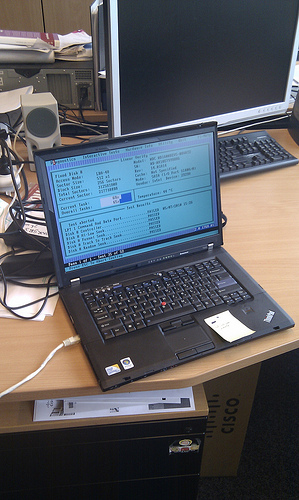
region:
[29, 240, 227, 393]
a black computer on the table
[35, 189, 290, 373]
a black computer on the table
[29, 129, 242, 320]
a black computer on the table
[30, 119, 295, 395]
One black laptop sitting on the desk.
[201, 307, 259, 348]
Yellow post it stuck to the key board.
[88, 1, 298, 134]
One large computer monitor sitting on the desk.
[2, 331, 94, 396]
White cable plugged into the laptop.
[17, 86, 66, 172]
Beige colored computer speaker.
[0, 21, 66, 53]
Textbook sitting on top of some paper.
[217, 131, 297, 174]
Black computer keyboard.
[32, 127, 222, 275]
Monitor of the laptop open and running.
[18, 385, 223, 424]
Stack of papers sitting on the shelf.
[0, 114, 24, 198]
White power supply with multiple plugs coming out of it.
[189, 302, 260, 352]
A post note on the computer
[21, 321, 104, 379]
an ethernet cable in the computer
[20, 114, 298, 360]
a laptop on the desk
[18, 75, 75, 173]
a speaker on the desk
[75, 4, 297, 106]
a monitor on the desk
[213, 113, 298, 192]
a keyboard on the desk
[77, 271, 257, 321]
a keyboard on the laptop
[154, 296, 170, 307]
a mouse button on the laptop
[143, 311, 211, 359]
a mouse pad on the laptop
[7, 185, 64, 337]
cables bundled up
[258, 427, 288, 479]
the floor is black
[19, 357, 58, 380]
the cord is white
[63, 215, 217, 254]
the laptop is on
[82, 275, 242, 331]
the laptop has a keyboard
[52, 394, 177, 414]
the papers are white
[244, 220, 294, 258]
the desk is brown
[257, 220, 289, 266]
the desk is wooden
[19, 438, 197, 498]
the cabinet is black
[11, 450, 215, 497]
the cabinet is under the desk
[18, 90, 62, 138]
the speaker is white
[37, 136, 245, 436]
a black laptop on a desk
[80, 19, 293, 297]
a computer monitor on a desk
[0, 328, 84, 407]
a cable connected to a laptop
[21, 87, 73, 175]
a computer speaker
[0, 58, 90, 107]
the back of a computer tower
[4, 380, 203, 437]
several papers on a cabinet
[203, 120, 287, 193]
a black computer keyboard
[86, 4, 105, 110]
a black paper folder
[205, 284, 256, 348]
a post it on a laptop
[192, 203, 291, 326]
a wooden desk